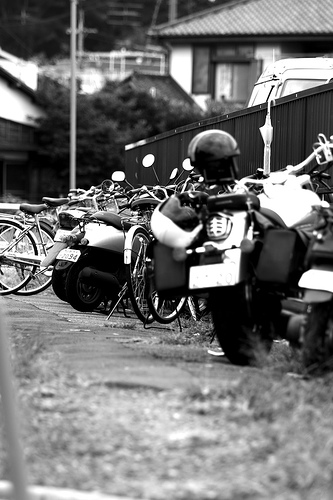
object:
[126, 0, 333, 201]
building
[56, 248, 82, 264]
license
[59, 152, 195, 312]
motorcycle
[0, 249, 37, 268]
spoke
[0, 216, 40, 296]
wheel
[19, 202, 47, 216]
seats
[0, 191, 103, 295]
bicycles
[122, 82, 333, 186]
fence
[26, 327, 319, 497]
grass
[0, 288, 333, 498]
ground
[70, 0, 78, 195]
pole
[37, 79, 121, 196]
bush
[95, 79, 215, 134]
bush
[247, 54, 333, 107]
van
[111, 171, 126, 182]
mirrors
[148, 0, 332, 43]
roof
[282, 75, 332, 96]
windows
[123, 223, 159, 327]
bike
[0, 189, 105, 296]
bike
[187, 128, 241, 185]
helmet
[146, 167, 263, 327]
bike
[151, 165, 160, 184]
poles